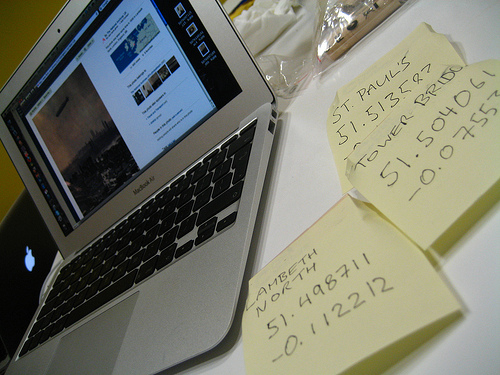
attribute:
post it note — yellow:
[239, 193, 462, 374]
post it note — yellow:
[349, 60, 499, 252]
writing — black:
[243, 243, 394, 365]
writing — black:
[349, 65, 498, 201]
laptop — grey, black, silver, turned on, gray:
[0, 0, 278, 374]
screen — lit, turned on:
[1, 0, 244, 235]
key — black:
[215, 211, 236, 232]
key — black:
[196, 179, 243, 227]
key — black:
[155, 240, 176, 270]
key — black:
[174, 239, 192, 257]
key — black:
[135, 253, 159, 283]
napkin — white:
[229, 0, 302, 55]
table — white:
[154, 0, 500, 374]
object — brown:
[322, 0, 404, 62]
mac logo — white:
[23, 245, 37, 272]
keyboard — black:
[18, 116, 258, 356]